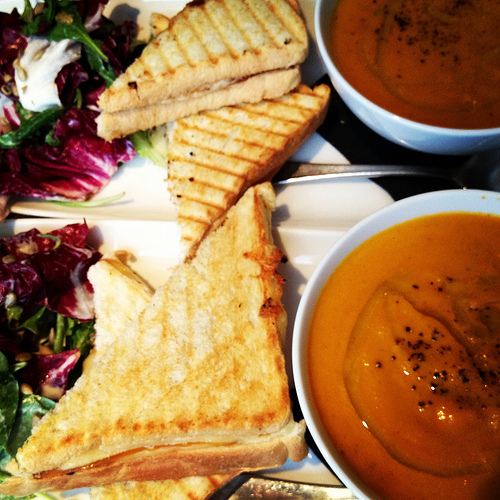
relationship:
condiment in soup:
[370, 279, 499, 405] [309, 213, 499, 496]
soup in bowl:
[309, 213, 499, 496] [291, 191, 499, 499]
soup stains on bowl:
[476, 194, 499, 207] [291, 191, 499, 499]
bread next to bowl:
[172, 84, 329, 256] [312, 1, 499, 155]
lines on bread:
[172, 94, 314, 240] [172, 84, 329, 256]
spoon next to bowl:
[267, 153, 499, 186] [291, 191, 499, 499]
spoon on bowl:
[267, 153, 499, 186] [312, 1, 499, 155]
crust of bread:
[300, 84, 328, 135] [172, 84, 329, 256]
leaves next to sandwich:
[1, 356, 52, 477] [18, 184, 307, 491]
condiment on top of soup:
[370, 279, 499, 405] [309, 213, 499, 496]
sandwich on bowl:
[18, 184, 307, 491] [312, 1, 499, 155]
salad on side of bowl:
[0, 0, 163, 213] [312, 1, 499, 155]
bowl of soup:
[291, 191, 499, 499] [309, 213, 499, 496]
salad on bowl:
[0, 0, 163, 213] [312, 1, 499, 155]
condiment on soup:
[370, 279, 499, 405] [309, 213, 499, 496]